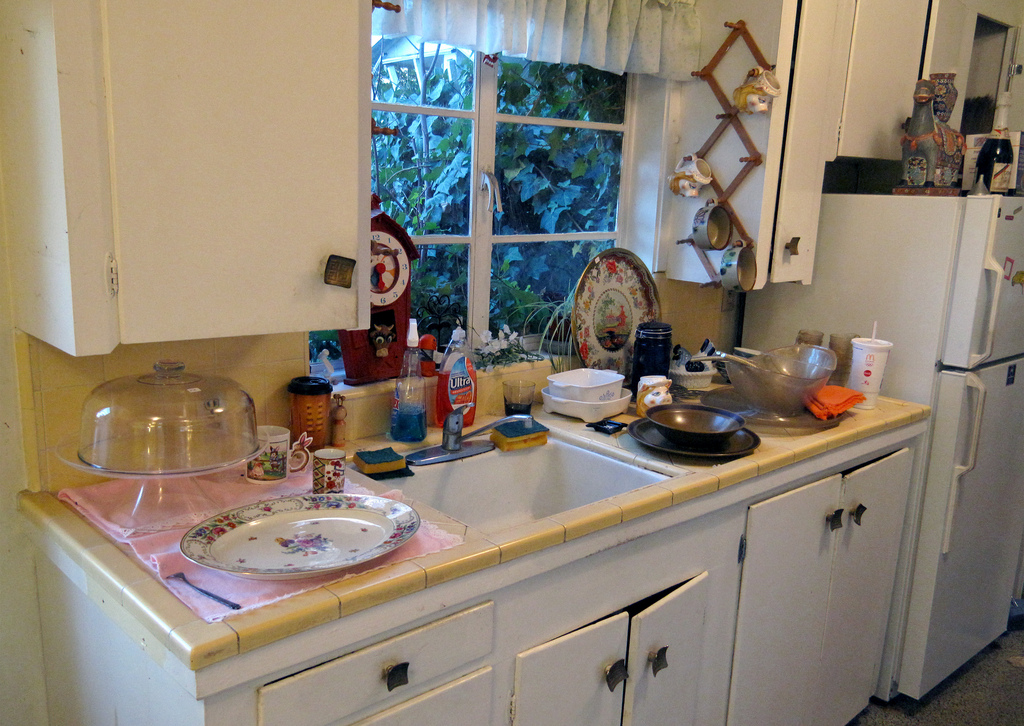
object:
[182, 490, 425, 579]
plate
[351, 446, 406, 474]
sponge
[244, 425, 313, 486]
cup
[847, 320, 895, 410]
cup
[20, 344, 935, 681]
counter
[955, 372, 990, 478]
handle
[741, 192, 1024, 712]
refrigerator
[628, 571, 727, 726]
cabinet door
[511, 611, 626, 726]
cabinet door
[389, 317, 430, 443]
plastic bottle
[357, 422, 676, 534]
sink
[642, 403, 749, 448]
bowl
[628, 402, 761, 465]
saucer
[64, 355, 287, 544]
cover.